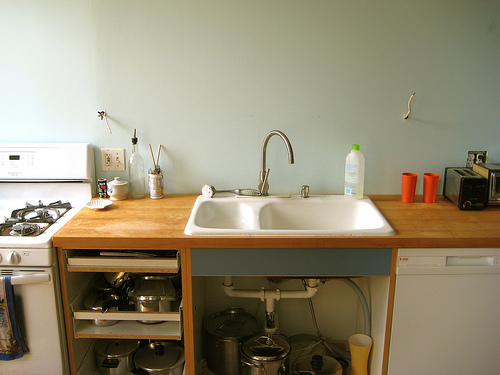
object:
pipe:
[221, 276, 317, 334]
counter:
[366, 195, 500, 245]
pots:
[288, 351, 344, 373]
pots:
[130, 339, 182, 375]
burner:
[11, 200, 72, 222]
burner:
[4, 220, 46, 238]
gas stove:
[0, 143, 95, 375]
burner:
[19, 197, 68, 217]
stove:
[0, 199, 72, 251]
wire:
[404, 93, 415, 120]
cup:
[345, 333, 372, 375]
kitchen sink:
[183, 194, 395, 237]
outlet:
[101, 148, 125, 172]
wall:
[0, 0, 500, 198]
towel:
[0, 277, 31, 362]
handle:
[0, 274, 50, 286]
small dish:
[85, 199, 112, 210]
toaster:
[442, 166, 488, 210]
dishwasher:
[389, 248, 500, 375]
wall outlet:
[466, 150, 488, 167]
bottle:
[344, 144, 365, 199]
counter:
[52, 193, 199, 244]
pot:
[91, 338, 140, 374]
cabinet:
[184, 244, 394, 375]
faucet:
[258, 129, 294, 195]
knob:
[7, 250, 21, 265]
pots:
[78, 270, 181, 328]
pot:
[203, 306, 259, 375]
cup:
[402, 172, 418, 202]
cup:
[423, 173, 439, 204]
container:
[148, 172, 164, 199]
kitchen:
[0, 0, 500, 375]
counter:
[0, 196, 89, 266]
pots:
[200, 300, 265, 372]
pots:
[237, 336, 290, 375]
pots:
[201, 307, 342, 374]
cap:
[353, 144, 360, 150]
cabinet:
[55, 238, 193, 375]